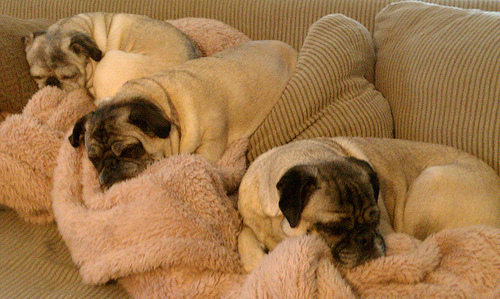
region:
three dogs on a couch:
[24, 12, 442, 256]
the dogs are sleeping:
[16, 17, 496, 241]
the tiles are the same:
[4, 98, 262, 276]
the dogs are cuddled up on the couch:
[9, 19, 499, 259]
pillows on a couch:
[260, 27, 388, 176]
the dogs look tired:
[23, 20, 400, 253]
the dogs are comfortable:
[28, 22, 420, 247]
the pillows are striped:
[311, 28, 499, 144]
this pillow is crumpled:
[237, 22, 408, 160]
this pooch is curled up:
[226, 105, 487, 265]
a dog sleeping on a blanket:
[236, 135, 498, 273]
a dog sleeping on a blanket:
[23, 8, 205, 93]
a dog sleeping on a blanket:
[81, 37, 298, 191]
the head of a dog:
[277, 152, 390, 268]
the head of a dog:
[66, 94, 177, 194]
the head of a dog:
[21, 27, 103, 99]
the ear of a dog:
[65, 27, 109, 63]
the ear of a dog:
[66, 115, 86, 150]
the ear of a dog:
[127, 96, 174, 141]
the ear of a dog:
[274, 165, 320, 237]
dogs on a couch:
[44, 9, 493, 287]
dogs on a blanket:
[18, 2, 474, 296]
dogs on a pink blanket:
[67, 13, 479, 293]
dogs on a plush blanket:
[7, 5, 496, 272]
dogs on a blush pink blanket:
[28, 1, 495, 263]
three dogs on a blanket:
[16, 11, 386, 293]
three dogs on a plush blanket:
[4, 6, 496, 281]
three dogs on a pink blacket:
[33, 21, 370, 294]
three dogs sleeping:
[26, 14, 494, 276]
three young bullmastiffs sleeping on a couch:
[9, 9, 499, 298]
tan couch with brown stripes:
[0, 0, 498, 296]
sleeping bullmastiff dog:
[234, 133, 499, 272]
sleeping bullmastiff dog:
[65, 39, 297, 191]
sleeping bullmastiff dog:
[21, 9, 201, 106]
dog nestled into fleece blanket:
[52, 39, 295, 297]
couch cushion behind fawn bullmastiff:
[235, 2, 498, 268]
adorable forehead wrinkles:
[322, 164, 372, 209]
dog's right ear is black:
[273, 156, 388, 266]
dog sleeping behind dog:
[22, 12, 298, 192]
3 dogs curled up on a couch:
[16, 2, 463, 283]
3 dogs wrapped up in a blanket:
[15, 11, 454, 286]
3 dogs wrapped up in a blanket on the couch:
[21, 0, 413, 280]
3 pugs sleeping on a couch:
[10, 9, 397, 269]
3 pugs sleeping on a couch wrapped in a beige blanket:
[5, 0, 412, 284]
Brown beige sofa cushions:
[285, 2, 497, 136]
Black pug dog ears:
[37, 81, 174, 146]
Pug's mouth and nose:
[327, 222, 383, 277]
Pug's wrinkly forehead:
[285, 151, 379, 216]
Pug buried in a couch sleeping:
[12, 1, 193, 108]